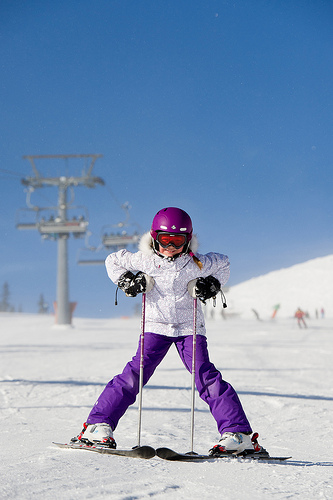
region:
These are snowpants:
[104, 347, 252, 443]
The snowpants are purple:
[105, 315, 255, 427]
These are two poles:
[125, 352, 298, 498]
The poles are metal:
[114, 368, 230, 448]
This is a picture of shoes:
[68, 408, 138, 483]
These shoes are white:
[210, 421, 287, 489]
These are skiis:
[59, 430, 149, 498]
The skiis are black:
[73, 424, 224, 495]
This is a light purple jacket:
[127, 295, 230, 330]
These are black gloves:
[113, 274, 156, 301]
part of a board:
[128, 444, 138, 453]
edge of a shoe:
[217, 438, 249, 461]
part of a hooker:
[184, 407, 199, 464]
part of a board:
[274, 444, 291, 478]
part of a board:
[160, 450, 177, 473]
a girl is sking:
[51, 197, 303, 468]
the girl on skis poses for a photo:
[50, 199, 294, 467]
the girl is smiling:
[51, 191, 292, 467]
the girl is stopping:
[47, 192, 292, 466]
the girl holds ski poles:
[44, 188, 296, 467]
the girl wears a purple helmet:
[52, 202, 293, 465]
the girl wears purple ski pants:
[57, 207, 302, 467]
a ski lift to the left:
[14, 144, 182, 327]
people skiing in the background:
[90, 280, 330, 338]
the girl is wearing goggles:
[50, 194, 290, 468]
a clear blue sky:
[34, 14, 218, 125]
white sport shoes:
[79, 412, 115, 461]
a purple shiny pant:
[93, 341, 248, 458]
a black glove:
[117, 267, 141, 297]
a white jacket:
[165, 270, 183, 320]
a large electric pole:
[23, 149, 88, 279]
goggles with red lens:
[157, 228, 190, 254]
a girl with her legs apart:
[69, 213, 250, 467]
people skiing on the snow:
[263, 292, 324, 328]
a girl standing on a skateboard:
[75, 204, 274, 497]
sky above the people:
[145, 67, 226, 139]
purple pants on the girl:
[95, 338, 261, 430]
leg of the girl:
[181, 331, 262, 457]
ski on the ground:
[31, 423, 155, 488]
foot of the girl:
[75, 414, 119, 446]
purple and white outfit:
[96, 206, 251, 379]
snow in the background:
[286, 256, 328, 285]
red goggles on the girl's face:
[153, 228, 189, 254]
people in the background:
[274, 294, 328, 339]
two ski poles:
[91, 293, 227, 477]